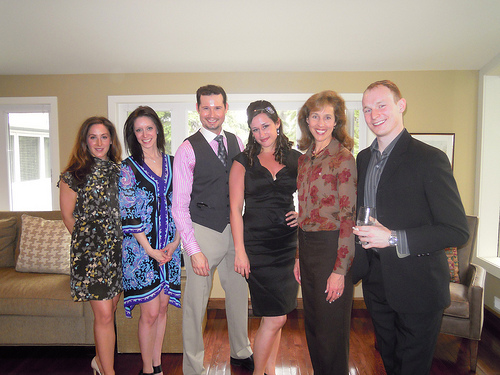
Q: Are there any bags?
A: No, there are no bags.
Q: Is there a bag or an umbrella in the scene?
A: No, there are no bags or umbrellas.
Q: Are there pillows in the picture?
A: Yes, there is a pillow.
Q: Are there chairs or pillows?
A: Yes, there is a pillow.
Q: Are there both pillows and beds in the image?
A: No, there is a pillow but no beds.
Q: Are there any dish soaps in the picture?
A: No, there are no dish soaps.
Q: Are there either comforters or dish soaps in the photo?
A: No, there are no dish soaps or comforters.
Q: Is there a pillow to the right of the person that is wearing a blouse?
A: Yes, there is a pillow to the right of the person.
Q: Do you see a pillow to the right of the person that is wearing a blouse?
A: Yes, there is a pillow to the right of the person.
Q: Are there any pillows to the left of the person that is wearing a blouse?
A: No, the pillow is to the right of the person.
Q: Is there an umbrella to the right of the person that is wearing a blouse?
A: No, there is a pillow to the right of the person.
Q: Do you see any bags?
A: No, there are no bags.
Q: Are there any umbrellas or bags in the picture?
A: No, there are no bags or umbrellas.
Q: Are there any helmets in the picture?
A: No, there are no helmets.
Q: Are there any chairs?
A: Yes, there is a chair.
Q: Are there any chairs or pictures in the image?
A: Yes, there is a chair.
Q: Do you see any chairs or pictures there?
A: Yes, there is a chair.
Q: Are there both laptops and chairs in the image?
A: No, there is a chair but no laptops.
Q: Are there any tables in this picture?
A: No, there are no tables.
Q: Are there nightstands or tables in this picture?
A: No, there are no tables or nightstands.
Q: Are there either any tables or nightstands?
A: No, there are no tables or nightstands.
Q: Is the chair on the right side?
A: Yes, the chair is on the right of the image.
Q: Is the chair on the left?
A: No, the chair is on the right of the image.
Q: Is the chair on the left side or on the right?
A: The chair is on the right of the image.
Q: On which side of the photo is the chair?
A: The chair is on the right of the image.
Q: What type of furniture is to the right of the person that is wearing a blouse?
A: The piece of furniture is a chair.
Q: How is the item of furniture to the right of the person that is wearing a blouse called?
A: The piece of furniture is a chair.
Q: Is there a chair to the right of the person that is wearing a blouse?
A: Yes, there is a chair to the right of the person.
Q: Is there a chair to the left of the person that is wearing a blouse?
A: No, the chair is to the right of the person.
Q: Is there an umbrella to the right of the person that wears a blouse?
A: No, there is a chair to the right of the person.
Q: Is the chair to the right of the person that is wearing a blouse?
A: Yes, the chair is to the right of the person.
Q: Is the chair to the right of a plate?
A: No, the chair is to the right of the person.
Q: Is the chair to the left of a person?
A: No, the chair is to the right of a person.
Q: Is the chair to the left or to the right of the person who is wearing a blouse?
A: The chair is to the right of the person.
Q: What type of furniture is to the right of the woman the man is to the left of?
A: The piece of furniture is a chair.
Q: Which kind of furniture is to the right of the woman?
A: The piece of furniture is a chair.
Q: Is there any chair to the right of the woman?
A: Yes, there is a chair to the right of the woman.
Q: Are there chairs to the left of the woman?
A: No, the chair is to the right of the woman.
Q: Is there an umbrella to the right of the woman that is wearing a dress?
A: No, there is a chair to the right of the woman.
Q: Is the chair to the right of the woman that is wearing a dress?
A: Yes, the chair is to the right of the woman.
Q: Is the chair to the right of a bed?
A: No, the chair is to the right of the woman.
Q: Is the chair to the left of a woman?
A: No, the chair is to the right of a woman.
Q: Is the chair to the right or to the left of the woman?
A: The chair is to the right of the woman.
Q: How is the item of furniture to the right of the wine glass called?
A: The piece of furniture is a chair.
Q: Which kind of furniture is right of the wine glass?
A: The piece of furniture is a chair.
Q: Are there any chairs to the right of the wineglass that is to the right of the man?
A: Yes, there is a chair to the right of the wine glass.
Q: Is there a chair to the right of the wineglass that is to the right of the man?
A: Yes, there is a chair to the right of the wine glass.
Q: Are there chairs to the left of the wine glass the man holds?
A: No, the chair is to the right of the wineglass.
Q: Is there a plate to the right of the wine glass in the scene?
A: No, there is a chair to the right of the wine glass.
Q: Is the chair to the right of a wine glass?
A: Yes, the chair is to the right of a wine glass.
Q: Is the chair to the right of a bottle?
A: No, the chair is to the right of a wine glass.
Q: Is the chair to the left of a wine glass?
A: No, the chair is to the right of a wine glass.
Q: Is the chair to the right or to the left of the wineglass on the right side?
A: The chair is to the right of the wine glass.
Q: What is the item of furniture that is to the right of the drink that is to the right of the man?
A: The piece of furniture is a chair.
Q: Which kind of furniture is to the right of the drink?
A: The piece of furniture is a chair.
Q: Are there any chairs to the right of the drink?
A: Yes, there is a chair to the right of the drink.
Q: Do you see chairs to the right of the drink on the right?
A: Yes, there is a chair to the right of the drink.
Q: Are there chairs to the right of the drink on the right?
A: Yes, there is a chair to the right of the drink.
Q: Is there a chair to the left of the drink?
A: No, the chair is to the right of the drink.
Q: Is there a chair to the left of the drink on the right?
A: No, the chair is to the right of the drink.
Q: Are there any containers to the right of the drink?
A: No, there is a chair to the right of the drink.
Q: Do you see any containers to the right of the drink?
A: No, there is a chair to the right of the drink.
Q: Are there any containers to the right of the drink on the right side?
A: No, there is a chair to the right of the drink.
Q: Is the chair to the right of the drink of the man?
A: Yes, the chair is to the right of the drink.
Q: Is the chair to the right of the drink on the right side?
A: Yes, the chair is to the right of the drink.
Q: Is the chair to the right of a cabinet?
A: No, the chair is to the right of the drink.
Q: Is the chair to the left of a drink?
A: No, the chair is to the right of a drink.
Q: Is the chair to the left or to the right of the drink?
A: The chair is to the right of the drink.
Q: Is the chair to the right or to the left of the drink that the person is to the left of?
A: The chair is to the right of the drink.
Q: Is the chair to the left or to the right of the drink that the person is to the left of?
A: The chair is to the right of the drink.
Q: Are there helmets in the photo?
A: No, there are no helmets.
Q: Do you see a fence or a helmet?
A: No, there are no helmets or fences.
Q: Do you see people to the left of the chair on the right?
A: Yes, there is a person to the left of the chair.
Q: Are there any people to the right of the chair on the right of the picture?
A: No, the person is to the left of the chair.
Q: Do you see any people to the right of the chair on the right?
A: No, the person is to the left of the chair.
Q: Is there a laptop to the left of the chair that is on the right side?
A: No, there is a person to the left of the chair.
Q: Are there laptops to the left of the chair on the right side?
A: No, there is a person to the left of the chair.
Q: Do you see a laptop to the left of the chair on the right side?
A: No, there is a person to the left of the chair.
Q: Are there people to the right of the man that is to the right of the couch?
A: Yes, there is a person to the right of the man.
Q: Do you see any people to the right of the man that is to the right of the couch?
A: Yes, there is a person to the right of the man.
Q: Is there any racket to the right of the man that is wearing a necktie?
A: No, there is a person to the right of the man.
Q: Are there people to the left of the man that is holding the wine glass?
A: Yes, there is a person to the left of the man.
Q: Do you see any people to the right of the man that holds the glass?
A: No, the person is to the left of the man.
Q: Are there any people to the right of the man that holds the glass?
A: No, the person is to the left of the man.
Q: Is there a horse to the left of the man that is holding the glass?
A: No, there is a person to the left of the man.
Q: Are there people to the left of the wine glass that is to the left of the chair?
A: Yes, there is a person to the left of the wineglass.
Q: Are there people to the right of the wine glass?
A: No, the person is to the left of the wine glass.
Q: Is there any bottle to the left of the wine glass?
A: No, there is a person to the left of the wine glass.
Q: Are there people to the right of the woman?
A: Yes, there is a person to the right of the woman.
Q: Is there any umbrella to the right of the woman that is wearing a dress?
A: No, there is a person to the right of the woman.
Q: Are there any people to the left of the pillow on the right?
A: Yes, there is a person to the left of the pillow.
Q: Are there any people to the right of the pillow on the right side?
A: No, the person is to the left of the pillow.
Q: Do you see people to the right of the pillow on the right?
A: No, the person is to the left of the pillow.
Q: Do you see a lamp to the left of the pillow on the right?
A: No, there is a person to the left of the pillow.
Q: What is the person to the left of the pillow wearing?
A: The person is wearing a blouse.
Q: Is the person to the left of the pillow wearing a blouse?
A: Yes, the person is wearing a blouse.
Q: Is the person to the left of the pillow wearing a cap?
A: No, the person is wearing a blouse.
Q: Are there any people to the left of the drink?
A: Yes, there is a person to the left of the drink.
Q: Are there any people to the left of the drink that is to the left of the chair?
A: Yes, there is a person to the left of the drink.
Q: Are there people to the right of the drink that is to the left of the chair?
A: No, the person is to the left of the drink.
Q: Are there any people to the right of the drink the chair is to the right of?
A: No, the person is to the left of the drink.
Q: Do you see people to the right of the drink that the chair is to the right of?
A: No, the person is to the left of the drink.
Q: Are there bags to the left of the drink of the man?
A: No, there is a person to the left of the drink.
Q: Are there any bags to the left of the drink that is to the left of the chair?
A: No, there is a person to the left of the drink.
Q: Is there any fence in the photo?
A: No, there are no fences.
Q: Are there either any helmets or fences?
A: No, there are no fences or helmets.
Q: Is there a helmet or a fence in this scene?
A: No, there are no fences or helmets.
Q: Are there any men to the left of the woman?
A: Yes, there is a man to the left of the woman.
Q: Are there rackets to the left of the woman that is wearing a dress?
A: No, there is a man to the left of the woman.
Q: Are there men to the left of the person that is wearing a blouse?
A: Yes, there is a man to the left of the person.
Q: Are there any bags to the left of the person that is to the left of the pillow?
A: No, there is a man to the left of the person.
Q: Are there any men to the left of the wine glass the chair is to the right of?
A: Yes, there is a man to the left of the wine glass.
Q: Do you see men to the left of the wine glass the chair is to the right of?
A: Yes, there is a man to the left of the wine glass.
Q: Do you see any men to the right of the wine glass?
A: No, the man is to the left of the wine glass.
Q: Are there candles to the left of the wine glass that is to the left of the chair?
A: No, there is a man to the left of the wineglass.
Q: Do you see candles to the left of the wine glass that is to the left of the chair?
A: No, there is a man to the left of the wineglass.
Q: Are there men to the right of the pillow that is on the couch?
A: Yes, there is a man to the right of the pillow.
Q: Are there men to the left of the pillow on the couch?
A: No, the man is to the right of the pillow.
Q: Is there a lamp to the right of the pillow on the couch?
A: No, there is a man to the right of the pillow.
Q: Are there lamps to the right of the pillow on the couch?
A: No, there is a man to the right of the pillow.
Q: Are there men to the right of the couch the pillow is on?
A: Yes, there is a man to the right of the couch.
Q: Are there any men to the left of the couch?
A: No, the man is to the right of the couch.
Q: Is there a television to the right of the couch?
A: No, there is a man to the right of the couch.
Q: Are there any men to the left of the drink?
A: Yes, there is a man to the left of the drink.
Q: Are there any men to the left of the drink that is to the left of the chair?
A: Yes, there is a man to the left of the drink.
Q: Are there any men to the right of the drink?
A: No, the man is to the left of the drink.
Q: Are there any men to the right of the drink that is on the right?
A: No, the man is to the left of the drink.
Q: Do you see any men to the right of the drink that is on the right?
A: No, the man is to the left of the drink.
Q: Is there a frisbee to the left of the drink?
A: No, there is a man to the left of the drink.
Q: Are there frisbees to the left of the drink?
A: No, there is a man to the left of the drink.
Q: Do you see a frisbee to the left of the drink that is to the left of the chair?
A: No, there is a man to the left of the drink.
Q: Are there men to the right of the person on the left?
A: Yes, there is a man to the right of the person.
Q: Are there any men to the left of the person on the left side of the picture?
A: No, the man is to the right of the person.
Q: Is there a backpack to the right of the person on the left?
A: No, there is a man to the right of the person.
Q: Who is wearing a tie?
A: The man is wearing a tie.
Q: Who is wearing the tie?
A: The man is wearing a tie.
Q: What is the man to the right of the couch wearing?
A: The man is wearing a necktie.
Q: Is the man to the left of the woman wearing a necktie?
A: Yes, the man is wearing a necktie.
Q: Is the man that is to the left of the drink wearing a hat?
A: No, the man is wearing a necktie.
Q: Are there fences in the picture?
A: No, there are no fences.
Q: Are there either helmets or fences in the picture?
A: No, there are no fences or helmets.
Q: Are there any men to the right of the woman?
A: Yes, there is a man to the right of the woman.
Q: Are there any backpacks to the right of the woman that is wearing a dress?
A: No, there is a man to the right of the woman.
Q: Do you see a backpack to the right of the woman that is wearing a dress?
A: No, there is a man to the right of the woman.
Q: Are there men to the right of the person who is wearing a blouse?
A: Yes, there is a man to the right of the person.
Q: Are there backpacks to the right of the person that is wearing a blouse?
A: No, there is a man to the right of the person.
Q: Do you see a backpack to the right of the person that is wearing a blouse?
A: No, there is a man to the right of the person.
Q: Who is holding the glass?
A: The man is holding the glass.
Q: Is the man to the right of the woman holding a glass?
A: Yes, the man is holding a glass.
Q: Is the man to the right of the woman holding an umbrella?
A: No, the man is holding a glass.